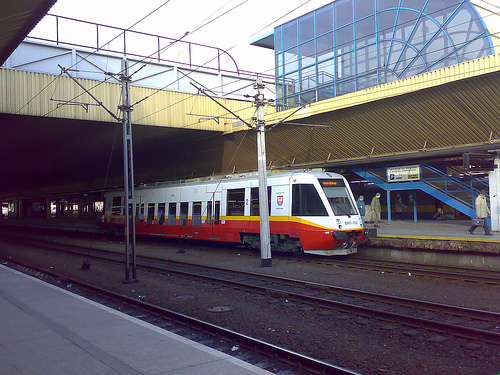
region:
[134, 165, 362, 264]
orange and white train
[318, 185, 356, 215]
windshield of the train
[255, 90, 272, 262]
white pole on the right side of the train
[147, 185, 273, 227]
windows on the right side of the train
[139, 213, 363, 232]
gold strip on the side of the train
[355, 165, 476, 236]
blue steps in the train station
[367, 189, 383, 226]
man walking on the plateform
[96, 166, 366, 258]
a train in the station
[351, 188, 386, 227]
men at a train station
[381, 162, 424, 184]
a sign for the train station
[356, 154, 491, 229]
a blue stair case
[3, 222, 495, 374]
long empty train tracks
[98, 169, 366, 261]
a train with lots of windows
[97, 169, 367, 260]
a red and yellow train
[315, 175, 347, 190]
an orange and black sign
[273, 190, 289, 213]
a logo on a train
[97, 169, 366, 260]
a train with a yellow stripe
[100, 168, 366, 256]
white and red train on tracks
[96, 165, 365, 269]
train stopped on train tracks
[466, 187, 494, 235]
man walking with a briefcase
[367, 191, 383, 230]
man with a long coat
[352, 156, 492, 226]
blue metal staircase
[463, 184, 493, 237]
man wearing a black hat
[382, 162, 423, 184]
white sign on side of staircase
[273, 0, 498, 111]
wall made of windows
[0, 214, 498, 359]
two lanes of train tracks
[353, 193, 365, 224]
person in blue jacket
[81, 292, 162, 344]
The platform has a white stripe.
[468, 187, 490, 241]
The man is walking on the platform.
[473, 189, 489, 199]
The man is wearing a hat.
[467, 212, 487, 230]
The man is carrying a brief case.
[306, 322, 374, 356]
The gravel is between the tracks.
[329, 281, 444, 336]
The railroad tracks are made of steel.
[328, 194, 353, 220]
The windshield wiper is black in color.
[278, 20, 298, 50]
window on a building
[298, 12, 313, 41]
window on a building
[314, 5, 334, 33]
window on a building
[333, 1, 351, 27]
window on a building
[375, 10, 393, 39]
window on a building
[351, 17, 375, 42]
window on a building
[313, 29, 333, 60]
window on a building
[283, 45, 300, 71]
window on a building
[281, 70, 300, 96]
window on a building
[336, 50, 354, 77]
window on a building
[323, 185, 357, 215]
window on a train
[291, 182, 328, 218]
window on a train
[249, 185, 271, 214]
window on a train